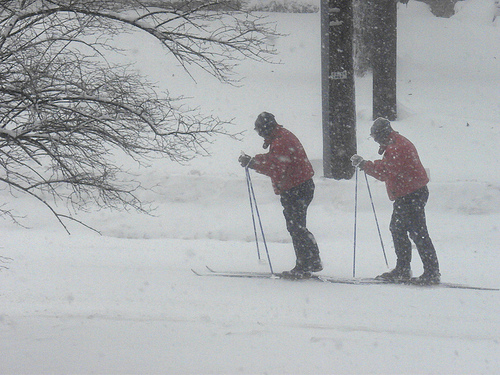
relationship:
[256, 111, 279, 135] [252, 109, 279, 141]
cap on head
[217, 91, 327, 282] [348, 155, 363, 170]
man wearing glove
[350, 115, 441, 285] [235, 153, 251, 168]
man wearing glove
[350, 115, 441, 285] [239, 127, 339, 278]
man wearing outfits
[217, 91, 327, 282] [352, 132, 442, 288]
man wearing outfits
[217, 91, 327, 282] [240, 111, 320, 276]
man wearing ski gear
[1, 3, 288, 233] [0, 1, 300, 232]
branches of tree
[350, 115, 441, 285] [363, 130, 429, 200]
man wearing red jacket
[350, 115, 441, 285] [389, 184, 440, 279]
man wearing black pants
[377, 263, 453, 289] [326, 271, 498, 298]
feet attached to skis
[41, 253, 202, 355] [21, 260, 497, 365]
snow sitting on ground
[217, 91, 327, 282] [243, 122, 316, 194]
man wearing red jacket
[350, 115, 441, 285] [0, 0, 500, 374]
man marching on snow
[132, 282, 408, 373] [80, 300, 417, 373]
snow on ground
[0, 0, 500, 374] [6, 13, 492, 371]
snow on ground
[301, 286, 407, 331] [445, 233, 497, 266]
snow on ground